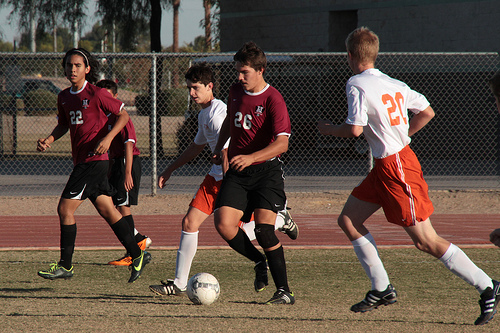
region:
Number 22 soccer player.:
[36, 48, 151, 282]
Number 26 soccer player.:
[211, 43, 296, 304]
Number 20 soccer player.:
[316, 26, 498, 323]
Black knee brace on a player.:
[254, 222, 279, 248]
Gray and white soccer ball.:
[188, 271, 219, 303]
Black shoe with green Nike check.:
[129, 252, 151, 283]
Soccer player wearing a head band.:
[38, 48, 150, 282]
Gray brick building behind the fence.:
[221, 3, 499, 163]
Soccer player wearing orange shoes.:
[95, 78, 152, 263]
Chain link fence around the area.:
[0, 50, 499, 196]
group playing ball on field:
[27, 42, 498, 317]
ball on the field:
[176, 260, 226, 306]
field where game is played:
[18, 252, 480, 332]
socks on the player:
[346, 233, 487, 288]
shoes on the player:
[346, 284, 499, 328]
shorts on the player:
[349, 153, 431, 213]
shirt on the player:
[220, 88, 289, 160]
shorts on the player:
[207, 161, 289, 206]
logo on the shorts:
[270, 198, 287, 211]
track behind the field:
[1, 207, 491, 254]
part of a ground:
[350, 255, 364, 295]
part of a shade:
[309, 280, 340, 319]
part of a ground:
[312, 275, 344, 310]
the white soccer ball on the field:
[185, 262, 222, 307]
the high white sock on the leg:
[169, 226, 201, 296]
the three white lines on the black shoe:
[356, 291, 381, 307]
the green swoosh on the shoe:
[131, 249, 147, 274]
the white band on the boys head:
[64, 46, 98, 90]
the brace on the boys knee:
[249, 219, 281, 248]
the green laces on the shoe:
[46, 257, 62, 271]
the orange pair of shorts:
[343, 149, 453, 224]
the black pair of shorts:
[213, 158, 290, 214]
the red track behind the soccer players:
[3, 210, 58, 252]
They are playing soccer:
[0, 30, 428, 306]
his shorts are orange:
[370, 145, 422, 227]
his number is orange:
[381, 89, 407, 128]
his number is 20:
[384, 80, 417, 130]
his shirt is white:
[333, 75, 425, 147]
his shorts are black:
[208, 163, 281, 211]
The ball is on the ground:
[180, 254, 264, 316]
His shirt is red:
[216, 90, 282, 144]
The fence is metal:
[6, 45, 496, 216]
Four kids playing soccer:
[31, 23, 446, 332]